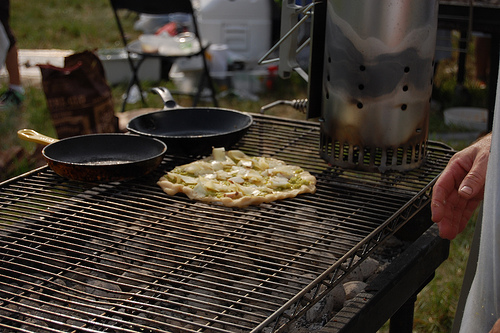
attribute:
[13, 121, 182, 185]
pan — black